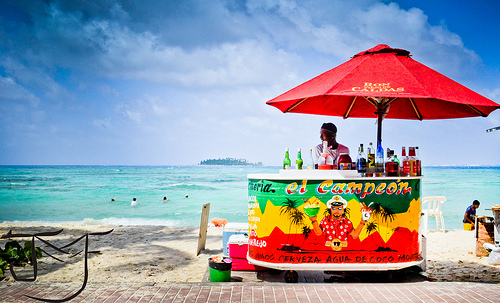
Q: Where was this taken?
A: A beach.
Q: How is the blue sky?
A: Cloudy.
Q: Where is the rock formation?
A: The background.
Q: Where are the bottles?
A: On counter.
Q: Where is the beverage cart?
A: On beach.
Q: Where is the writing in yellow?
A: On umbrella.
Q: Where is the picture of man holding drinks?
A: On cart.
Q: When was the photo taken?
A: In the afternoon.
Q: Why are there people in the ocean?
A: They are swimming.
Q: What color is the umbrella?
A: Red.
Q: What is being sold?
A: Drinks.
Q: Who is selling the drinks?
A: An Employee.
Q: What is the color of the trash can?
A: Green.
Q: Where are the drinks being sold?
A: On the beach.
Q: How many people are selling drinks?
A: One.